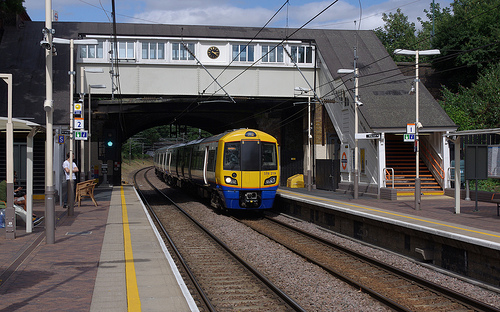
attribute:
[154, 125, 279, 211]
train is yellow — blue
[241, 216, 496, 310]
train rail — Two train, metal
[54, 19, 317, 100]
bridge — windows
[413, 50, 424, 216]
electric pole — tall, silver, gray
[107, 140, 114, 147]
traffic light — green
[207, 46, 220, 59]
clock — black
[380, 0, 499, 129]
trees with leaves — green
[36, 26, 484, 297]
station — train 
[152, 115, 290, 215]
train — yellow, blue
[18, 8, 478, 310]
station — train 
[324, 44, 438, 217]
pole — Electric 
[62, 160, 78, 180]
arms — crossed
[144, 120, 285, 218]
train — yellow, blue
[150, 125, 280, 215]
train — yellow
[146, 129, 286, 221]
train — blue, yellow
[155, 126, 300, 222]
train — blue, yellow